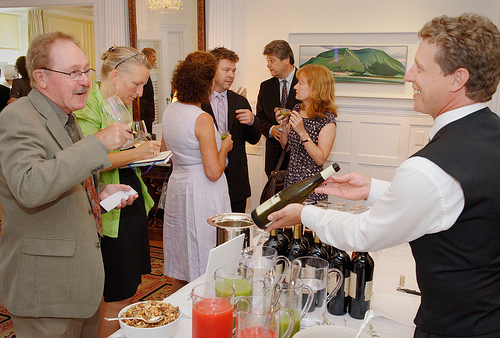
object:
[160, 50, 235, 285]
woman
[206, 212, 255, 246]
silver plate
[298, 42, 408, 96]
picture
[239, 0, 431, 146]
wall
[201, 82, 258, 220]
suit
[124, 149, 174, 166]
notebook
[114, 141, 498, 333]
plate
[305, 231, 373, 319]
wine bottles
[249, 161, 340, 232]
champagne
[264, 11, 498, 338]
waiter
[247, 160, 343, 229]
wine bottle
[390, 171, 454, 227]
shirt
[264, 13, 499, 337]
man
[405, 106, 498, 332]
vest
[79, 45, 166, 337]
woman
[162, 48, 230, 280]
lady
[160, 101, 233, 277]
dress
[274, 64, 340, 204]
woman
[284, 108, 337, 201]
dress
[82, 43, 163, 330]
lady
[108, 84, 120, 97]
earring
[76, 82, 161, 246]
jacket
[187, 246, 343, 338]
pitcher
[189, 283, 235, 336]
drink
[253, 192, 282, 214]
label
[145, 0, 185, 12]
chandelier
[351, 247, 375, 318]
bottle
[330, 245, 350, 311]
bottle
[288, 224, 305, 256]
bottle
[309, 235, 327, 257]
bottle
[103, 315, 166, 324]
spoon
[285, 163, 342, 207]
bottle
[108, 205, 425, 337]
table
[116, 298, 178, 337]
bowl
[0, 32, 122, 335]
man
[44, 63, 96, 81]
glasses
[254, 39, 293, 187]
man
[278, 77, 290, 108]
tie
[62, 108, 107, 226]
tie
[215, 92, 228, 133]
tie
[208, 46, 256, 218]
man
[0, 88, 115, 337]
suit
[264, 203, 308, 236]
hand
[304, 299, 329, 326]
water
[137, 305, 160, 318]
food